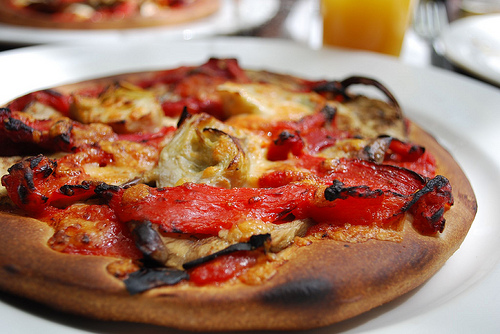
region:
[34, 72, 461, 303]
ROUND PIZZA ON WHITE PLATE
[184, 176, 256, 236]
RED PEPPERONI ON PIZZA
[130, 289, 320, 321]
GOLDEN CRUST OF PIZZA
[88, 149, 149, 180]
MELTED CHEESE ON PIZZA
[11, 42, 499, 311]
ROUND WHITE PLATE ON TABLE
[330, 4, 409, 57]
GLASS OF ORANGE JUICE ON TABLE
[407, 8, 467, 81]
METAL FORK ON TABLE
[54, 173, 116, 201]
BURNT EDGES OF PEPPERONI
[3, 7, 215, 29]
SECOND PIZZA ON TABLE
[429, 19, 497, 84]
WHITE ROUND PLATE ON RIGHT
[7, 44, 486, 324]
a slightly burnt pizza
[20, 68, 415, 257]
red stuff on a pizza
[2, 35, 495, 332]
a round white plate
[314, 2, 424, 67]
a glass of orange juice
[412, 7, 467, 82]
a fork by a plate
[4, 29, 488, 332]
a small round pizza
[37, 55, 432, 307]
melted cheese on pizza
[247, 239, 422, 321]
an over cooked section of crust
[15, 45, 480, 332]
a round pizza on a round plate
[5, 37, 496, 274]
a white plate with pizza on it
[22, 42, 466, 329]
small personal pizza on plate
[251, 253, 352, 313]
black crust on pizza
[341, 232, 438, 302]
brown crust on a pizza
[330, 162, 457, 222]
red topping on pizza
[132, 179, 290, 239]
red pepper on top of pizza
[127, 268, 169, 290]
black burnt topping on pizza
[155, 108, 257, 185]
yellow vegetables on pizza top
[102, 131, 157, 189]
orange cheese on pizza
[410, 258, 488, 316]
white plate below pizza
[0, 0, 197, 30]
pizza on another plate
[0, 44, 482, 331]
pizza with burnt crust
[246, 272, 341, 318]
black spot on a pizza crust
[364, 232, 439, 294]
black spot on a pizza crust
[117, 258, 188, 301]
black spot on a pizza crust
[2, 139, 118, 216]
charred vegetable on a pizza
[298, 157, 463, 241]
charred vegetable on a pizza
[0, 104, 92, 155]
charred vegetable on a pizza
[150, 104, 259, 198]
charred vegetable on a pizza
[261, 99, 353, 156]
charred vegetable on a pizza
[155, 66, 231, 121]
charred vegetable on a pizza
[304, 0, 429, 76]
glass of juice behind pizza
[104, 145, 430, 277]
red tomatoes on pizza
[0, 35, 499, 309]
round vegetable pizza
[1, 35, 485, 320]
pizza on white plate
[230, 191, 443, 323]
burnt crust on pizza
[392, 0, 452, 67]
fork beside glass of juice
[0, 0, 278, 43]
another plate of pizza behind first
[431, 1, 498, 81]
white plate in behind corner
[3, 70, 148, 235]
charred tomatoes on pizza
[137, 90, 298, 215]
artichoke on pizza